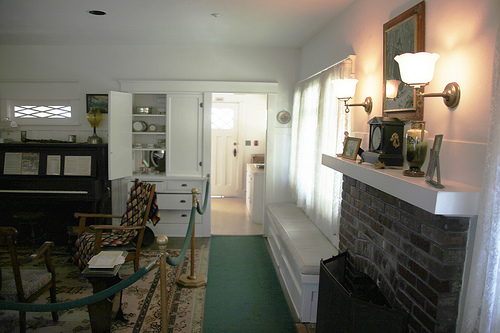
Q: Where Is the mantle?
A: Above fireplace.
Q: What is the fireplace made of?
A: Brick.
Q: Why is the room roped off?
A: It's for show.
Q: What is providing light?
A: Two wall lamps.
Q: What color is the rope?
A: Green.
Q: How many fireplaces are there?
A: One.